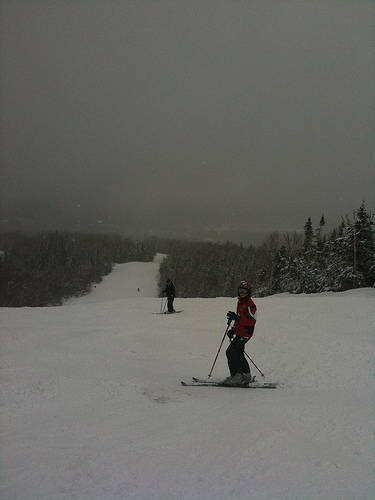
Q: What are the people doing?
A: Skiing.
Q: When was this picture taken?
A: During the day.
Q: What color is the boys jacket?
A: Red.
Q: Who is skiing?
A: The people.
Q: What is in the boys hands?
A: Ski poles.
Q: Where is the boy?
A: On a ski slope.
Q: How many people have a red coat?
A: One.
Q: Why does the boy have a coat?
A: It's cold.